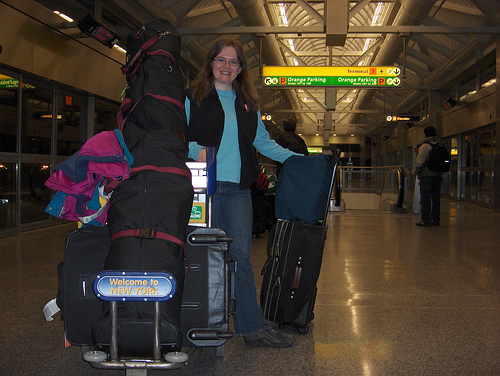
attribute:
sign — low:
[93, 270, 179, 304]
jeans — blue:
[208, 169, 279, 339]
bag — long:
[96, 25, 186, 350]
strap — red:
[131, 42, 180, 67]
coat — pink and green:
[45, 128, 134, 225]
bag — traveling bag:
[255, 133, 345, 340]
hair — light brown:
[198, 35, 255, 109]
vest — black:
[187, 84, 258, 186]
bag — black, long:
[87, 13, 196, 360]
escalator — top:
[334, 162, 407, 214]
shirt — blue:
[186, 100, 270, 192]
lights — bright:
[267, 0, 395, 122]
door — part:
[467, 129, 497, 200]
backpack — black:
[419, 139, 444, 174]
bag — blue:
[272, 142, 334, 227]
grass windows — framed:
[18, 77, 110, 142]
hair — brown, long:
[183, 37, 258, 111]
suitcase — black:
[259, 213, 328, 336]